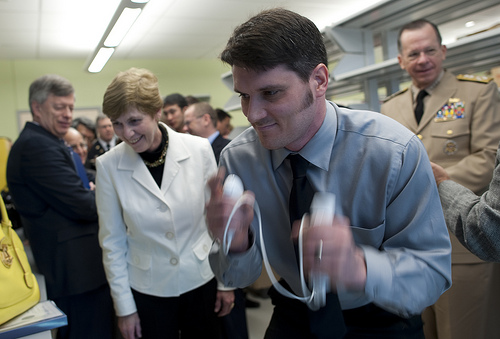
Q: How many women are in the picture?
A: One.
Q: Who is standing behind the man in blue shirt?
A: A man in uniform.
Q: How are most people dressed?
A: In business attires.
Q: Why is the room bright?
A: The lights are on.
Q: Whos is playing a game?
A: A man in blue shirt.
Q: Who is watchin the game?
A: A woman in white jacket.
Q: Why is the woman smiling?
A: She enjoys watching the game.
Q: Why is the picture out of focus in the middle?
A: The man is moving his arms.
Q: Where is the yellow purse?
A: In the left bottom corner.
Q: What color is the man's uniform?
A: Brown.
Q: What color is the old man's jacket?
A: Black.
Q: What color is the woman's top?
A: White.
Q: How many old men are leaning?
A: One.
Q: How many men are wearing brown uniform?
A: One.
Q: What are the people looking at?
A: Television.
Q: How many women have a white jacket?
A: One.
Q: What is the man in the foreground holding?
A: Wii remote.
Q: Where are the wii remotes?
A: In the man in the blue shirts hands.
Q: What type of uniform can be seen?
A: Military.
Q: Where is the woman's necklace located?
A: Around her neck.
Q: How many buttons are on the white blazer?
A: 3.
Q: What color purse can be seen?
A: Yellow.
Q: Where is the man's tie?
A: Around neck.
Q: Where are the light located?
A: On ceiling.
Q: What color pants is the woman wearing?
A: Black.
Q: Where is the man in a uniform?
A: On the right.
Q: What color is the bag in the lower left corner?
A: Yellow.